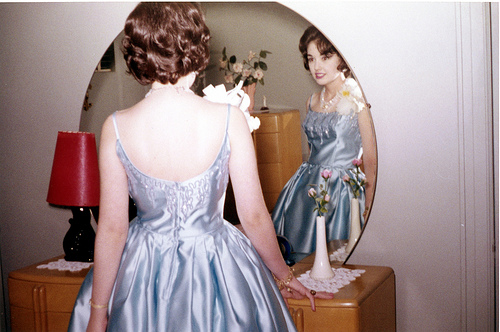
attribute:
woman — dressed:
[85, 0, 319, 331]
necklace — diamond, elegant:
[319, 78, 354, 105]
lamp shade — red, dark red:
[48, 130, 102, 207]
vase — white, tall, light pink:
[309, 216, 337, 281]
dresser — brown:
[5, 253, 394, 330]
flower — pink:
[253, 70, 265, 81]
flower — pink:
[233, 62, 245, 75]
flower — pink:
[223, 74, 235, 85]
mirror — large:
[79, 0, 379, 268]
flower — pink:
[322, 168, 332, 184]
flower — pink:
[307, 187, 319, 199]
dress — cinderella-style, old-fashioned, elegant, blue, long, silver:
[71, 112, 294, 331]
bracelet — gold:
[280, 268, 299, 289]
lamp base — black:
[62, 206, 99, 261]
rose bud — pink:
[324, 192, 331, 203]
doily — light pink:
[294, 260, 367, 294]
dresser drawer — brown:
[7, 278, 93, 312]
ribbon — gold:
[86, 303, 112, 311]